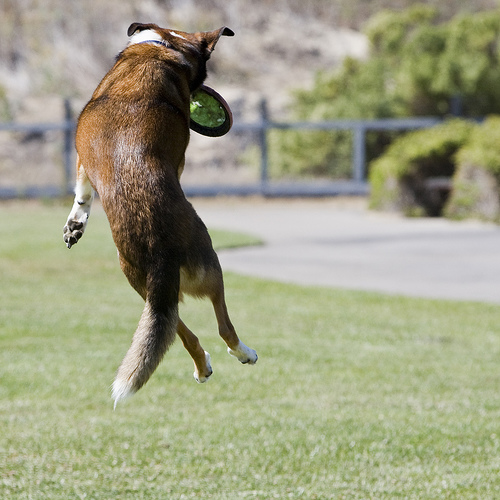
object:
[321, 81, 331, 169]
tree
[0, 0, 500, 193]
mountain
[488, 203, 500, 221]
rocks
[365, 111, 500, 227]
weeds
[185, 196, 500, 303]
driveway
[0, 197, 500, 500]
ground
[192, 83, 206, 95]
dog's mouth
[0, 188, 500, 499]
property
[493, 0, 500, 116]
tree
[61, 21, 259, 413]
dog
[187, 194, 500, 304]
walkway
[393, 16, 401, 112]
trees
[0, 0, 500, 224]
background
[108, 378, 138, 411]
tip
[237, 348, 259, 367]
dog's paws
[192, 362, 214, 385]
dog's paws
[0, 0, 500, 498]
air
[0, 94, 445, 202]
fence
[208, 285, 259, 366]
legs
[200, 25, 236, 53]
ear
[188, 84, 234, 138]
frisbee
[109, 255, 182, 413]
tail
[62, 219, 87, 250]
pad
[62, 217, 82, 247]
paw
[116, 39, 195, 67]
neck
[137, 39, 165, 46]
collar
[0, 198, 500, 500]
grass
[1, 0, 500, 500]
park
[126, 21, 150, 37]
ear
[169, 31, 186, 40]
patch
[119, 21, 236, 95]
head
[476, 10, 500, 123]
bush